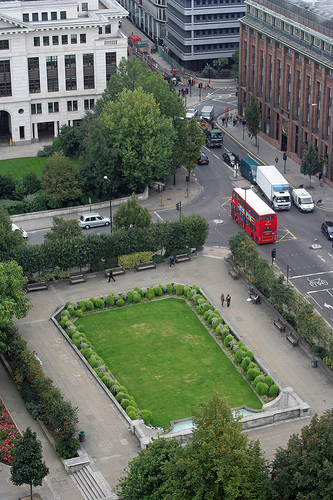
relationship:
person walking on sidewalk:
[226, 293, 231, 307] [9, 162, 201, 234]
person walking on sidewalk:
[219, 292, 225, 307] [9, 162, 201, 234]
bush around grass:
[146, 288, 154, 297] [73, 294, 266, 426]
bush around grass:
[175, 284, 183, 295] [73, 294, 266, 426]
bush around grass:
[267, 382, 280, 398] [73, 294, 266, 426]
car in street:
[75, 211, 111, 230] [110, 195, 213, 236]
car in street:
[197, 149, 209, 166] [279, 237, 331, 307]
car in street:
[317, 217, 332, 247] [282, 236, 328, 294]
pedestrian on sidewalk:
[107, 270, 116, 280] [64, 277, 134, 297]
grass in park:
[73, 297, 261, 427] [0, 212, 331, 498]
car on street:
[76, 211, 111, 230] [5, 188, 236, 253]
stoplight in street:
[170, 198, 187, 220] [276, 232, 326, 300]